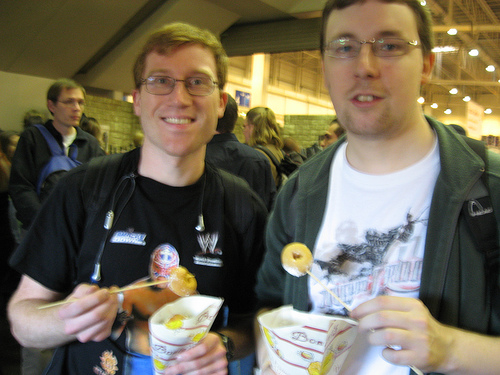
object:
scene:
[0, 0, 496, 375]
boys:
[7, 21, 265, 375]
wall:
[85, 90, 163, 168]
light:
[447, 28, 457, 35]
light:
[483, 63, 496, 73]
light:
[469, 49, 479, 56]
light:
[449, 88, 458, 94]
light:
[462, 94, 472, 102]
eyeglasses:
[325, 36, 422, 60]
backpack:
[36, 125, 85, 189]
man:
[10, 77, 106, 238]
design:
[309, 210, 433, 302]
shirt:
[307, 140, 440, 375]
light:
[417, 97, 425, 104]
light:
[430, 101, 439, 109]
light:
[444, 108, 452, 114]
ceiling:
[417, 2, 499, 140]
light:
[420, 4, 427, 7]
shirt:
[10, 150, 264, 375]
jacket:
[267, 111, 499, 371]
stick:
[299, 263, 424, 374]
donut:
[280, 242, 314, 277]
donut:
[168, 266, 198, 297]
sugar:
[169, 279, 179, 291]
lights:
[443, 109, 451, 115]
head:
[46, 79, 87, 126]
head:
[132, 22, 228, 157]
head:
[318, 2, 436, 140]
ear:
[47, 99, 55, 114]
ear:
[131, 89, 140, 116]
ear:
[218, 91, 228, 118]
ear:
[423, 51, 435, 84]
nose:
[165, 82, 194, 108]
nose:
[353, 43, 380, 78]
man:
[249, 0, 500, 375]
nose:
[73, 102, 81, 111]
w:
[195, 230, 222, 254]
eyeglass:
[136, 72, 222, 96]